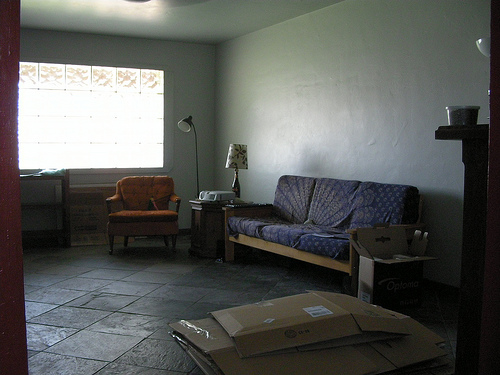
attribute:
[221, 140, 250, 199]
lamp — shorter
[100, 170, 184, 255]
chair — orange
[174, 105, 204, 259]
lamp — tall, floor, off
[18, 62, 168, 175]
window — large, glass, block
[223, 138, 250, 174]
shade — lamp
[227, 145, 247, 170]
pattern — floral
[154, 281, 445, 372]
boxes — flattened, cardboard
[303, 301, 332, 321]
label — shipping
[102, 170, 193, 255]
chair — vintage, orange, arm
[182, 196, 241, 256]
table — end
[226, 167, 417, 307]
futon — wooden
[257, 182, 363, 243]
cover — blue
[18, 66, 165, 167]
squares — tiny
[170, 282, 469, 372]
boxes — cardboard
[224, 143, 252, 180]
shade — lamp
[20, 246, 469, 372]
tiles — large, square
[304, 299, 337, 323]
label — white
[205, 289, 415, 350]
box — cardboard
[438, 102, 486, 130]
container — clear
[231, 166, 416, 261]
cushions — blue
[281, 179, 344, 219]
patterns — golden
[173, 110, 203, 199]
lamp — standing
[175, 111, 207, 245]
lamp — tall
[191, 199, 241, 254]
table — side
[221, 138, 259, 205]
lamp — small